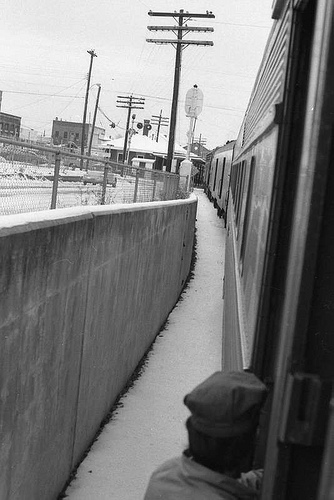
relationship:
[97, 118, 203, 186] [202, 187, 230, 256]
train depot next to tracks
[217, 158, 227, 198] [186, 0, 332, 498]
window on side of train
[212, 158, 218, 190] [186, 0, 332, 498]
window on side of train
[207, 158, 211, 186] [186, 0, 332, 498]
window on side of train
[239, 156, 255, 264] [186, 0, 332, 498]
window on side of train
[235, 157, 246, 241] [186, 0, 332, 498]
window on side of train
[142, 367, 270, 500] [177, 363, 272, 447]
people wearing cap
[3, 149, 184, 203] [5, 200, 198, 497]
metal fencing on top wall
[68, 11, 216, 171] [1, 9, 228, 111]
poles connected wires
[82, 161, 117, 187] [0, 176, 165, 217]
car on road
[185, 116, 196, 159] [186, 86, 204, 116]
pole supporting sign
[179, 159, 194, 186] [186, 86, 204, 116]
base supporting sign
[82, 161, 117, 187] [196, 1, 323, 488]
car driving train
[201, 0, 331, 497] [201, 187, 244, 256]
train moving in tracks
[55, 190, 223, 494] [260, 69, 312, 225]
snow covering train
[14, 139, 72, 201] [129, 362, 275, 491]
fence detour people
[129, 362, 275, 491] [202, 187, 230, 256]
people from being around tracks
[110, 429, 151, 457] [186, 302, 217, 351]
ice covers ground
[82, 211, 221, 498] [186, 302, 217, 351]
snow covers ground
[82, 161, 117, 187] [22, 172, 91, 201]
car on a street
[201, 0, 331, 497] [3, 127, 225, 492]
train pulled train station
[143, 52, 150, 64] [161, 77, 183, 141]
line on pole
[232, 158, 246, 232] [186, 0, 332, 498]
window on side of train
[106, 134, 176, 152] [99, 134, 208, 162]
snow covering roof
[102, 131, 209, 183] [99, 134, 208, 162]
building has roof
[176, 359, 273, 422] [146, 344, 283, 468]
hat on head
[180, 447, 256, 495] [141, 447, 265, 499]
collar on coat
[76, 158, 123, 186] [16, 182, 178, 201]
car driving on street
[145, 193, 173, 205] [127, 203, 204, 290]
snow on top of wall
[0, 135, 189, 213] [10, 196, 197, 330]
fence above wall